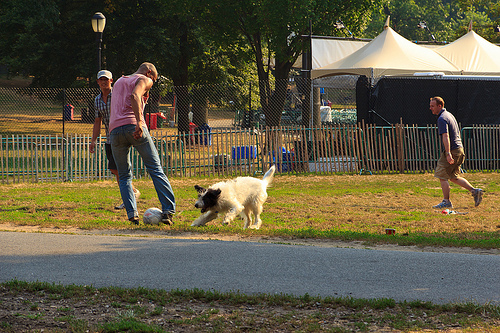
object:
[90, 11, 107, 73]
lamp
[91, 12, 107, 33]
globe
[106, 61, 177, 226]
man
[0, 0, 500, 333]
park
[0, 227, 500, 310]
path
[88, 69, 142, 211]
man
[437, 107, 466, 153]
shirt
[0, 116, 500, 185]
fencing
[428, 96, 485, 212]
man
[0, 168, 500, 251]
grass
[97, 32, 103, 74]
lamppost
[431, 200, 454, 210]
tennis shoes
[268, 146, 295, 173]
object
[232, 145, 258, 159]
object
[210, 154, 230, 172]
object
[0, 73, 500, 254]
ground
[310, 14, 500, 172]
tent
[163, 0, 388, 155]
trees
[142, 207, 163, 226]
ball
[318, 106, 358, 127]
stuff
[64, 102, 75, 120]
can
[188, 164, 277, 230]
dog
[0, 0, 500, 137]
background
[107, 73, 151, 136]
shirt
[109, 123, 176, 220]
jeans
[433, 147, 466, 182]
shorts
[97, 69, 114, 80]
cap